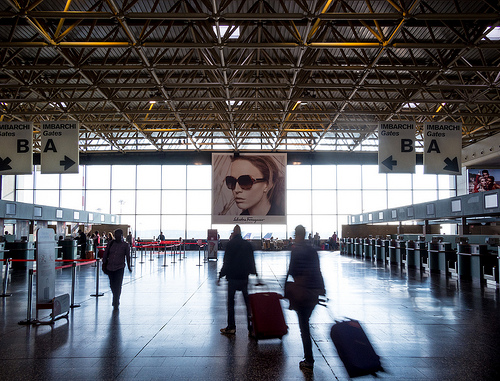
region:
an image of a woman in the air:
[207, 150, 299, 227]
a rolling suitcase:
[322, 310, 388, 380]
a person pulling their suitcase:
[279, 220, 389, 379]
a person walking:
[99, 225, 131, 305]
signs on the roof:
[376, 115, 468, 177]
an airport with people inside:
[4, 105, 496, 372]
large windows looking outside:
[17, 159, 462, 238]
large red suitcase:
[242, 284, 294, 341]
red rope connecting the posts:
[4, 231, 183, 296]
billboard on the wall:
[461, 152, 498, 192]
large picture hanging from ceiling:
[202, 145, 294, 235]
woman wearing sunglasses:
[203, 134, 290, 224]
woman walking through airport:
[90, 217, 142, 315]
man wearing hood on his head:
[211, 216, 283, 346]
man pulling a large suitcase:
[215, 213, 287, 348]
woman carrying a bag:
[272, 209, 354, 366]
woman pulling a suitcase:
[280, 219, 381, 374]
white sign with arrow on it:
[365, 112, 414, 177]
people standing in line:
[77, 221, 168, 246]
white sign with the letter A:
[425, 115, 465, 176]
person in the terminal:
[100, 226, 136, 314]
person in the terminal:
[212, 225, 262, 343]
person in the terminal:
[280, 223, 331, 375]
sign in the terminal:
[1, 121, 33, 175]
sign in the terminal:
[38, 118, 80, 176]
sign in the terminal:
[208, 150, 288, 226]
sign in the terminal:
[377, 119, 417, 173]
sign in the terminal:
[422, 119, 459, 174]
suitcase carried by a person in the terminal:
[244, 288, 289, 344]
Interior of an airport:
[0, 3, 497, 380]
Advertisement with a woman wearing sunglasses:
[211, 150, 286, 225]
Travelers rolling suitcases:
[213, 225, 386, 376]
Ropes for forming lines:
[11, 238, 208, 303]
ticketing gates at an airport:
[341, 201, 497, 296]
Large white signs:
[377, 120, 463, 173]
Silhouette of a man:
[99, 225, 134, 312]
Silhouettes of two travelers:
[216, 224, 393, 376]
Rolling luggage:
[245, 288, 290, 348]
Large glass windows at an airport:
[17, 163, 459, 240]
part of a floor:
[348, 295, 353, 302]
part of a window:
[325, 198, 333, 208]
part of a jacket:
[234, 256, 241, 286]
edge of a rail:
[379, 230, 382, 247]